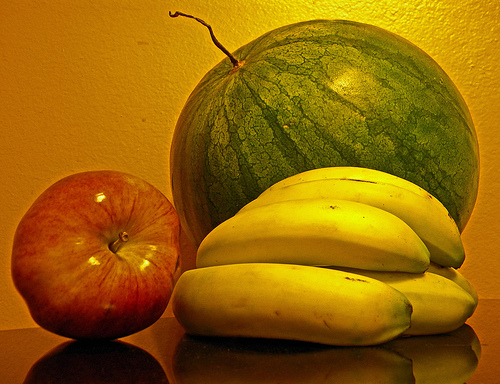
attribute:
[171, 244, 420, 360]
banana — yellow, ripe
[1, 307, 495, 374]
table — brown, wooden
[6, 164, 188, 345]
apple — red, shiny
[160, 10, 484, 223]
watermelon — green, large, round, circle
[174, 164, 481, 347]
bananas — yellow, ripe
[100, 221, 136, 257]
stem — small, dry, short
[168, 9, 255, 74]
stem — long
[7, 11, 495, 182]
wall — textured